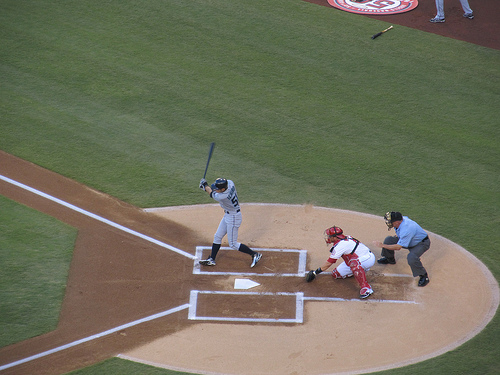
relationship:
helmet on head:
[209, 177, 229, 189] [210, 175, 233, 194]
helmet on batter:
[209, 177, 229, 189] [196, 171, 266, 274]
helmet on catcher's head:
[321, 227, 347, 241] [320, 225, 351, 246]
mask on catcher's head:
[322, 229, 336, 248] [320, 225, 351, 246]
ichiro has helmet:
[196, 171, 266, 274] [209, 177, 229, 189]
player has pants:
[196, 171, 266, 274] [211, 211, 246, 256]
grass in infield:
[1, 194, 79, 357] [1, 148, 211, 372]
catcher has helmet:
[298, 225, 381, 305] [321, 227, 347, 241]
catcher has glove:
[298, 225, 381, 305] [300, 264, 314, 287]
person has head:
[196, 171, 266, 274] [210, 175, 233, 194]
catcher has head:
[298, 225, 381, 305] [320, 225, 351, 246]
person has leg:
[196, 171, 266, 274] [225, 217, 265, 273]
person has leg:
[196, 171, 266, 274] [199, 216, 232, 267]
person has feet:
[196, 171, 266, 274] [195, 252, 267, 275]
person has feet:
[374, 209, 435, 289] [379, 249, 431, 290]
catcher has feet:
[298, 225, 381, 305] [355, 283, 377, 302]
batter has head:
[196, 171, 266, 274] [210, 175, 233, 194]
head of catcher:
[320, 225, 351, 246] [298, 225, 381, 305]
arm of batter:
[193, 177, 231, 204] [196, 171, 266, 274]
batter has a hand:
[196, 171, 266, 274] [197, 177, 209, 189]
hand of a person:
[372, 237, 388, 252] [374, 209, 435, 289]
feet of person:
[379, 249, 431, 290] [374, 209, 435, 289]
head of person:
[381, 208, 408, 229] [374, 209, 435, 289]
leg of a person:
[405, 240, 433, 289] [374, 209, 435, 289]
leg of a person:
[376, 235, 403, 267] [374, 209, 435, 289]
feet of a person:
[379, 249, 431, 290] [374, 209, 435, 289]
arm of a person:
[373, 239, 411, 252] [374, 209, 435, 289]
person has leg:
[374, 209, 435, 289] [376, 235, 403, 267]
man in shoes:
[374, 209, 435, 289] [379, 249, 431, 290]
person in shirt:
[374, 209, 435, 289] [391, 217, 429, 252]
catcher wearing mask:
[298, 225, 381, 305] [322, 230, 332, 248]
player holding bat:
[196, 171, 266, 274] [201, 137, 218, 188]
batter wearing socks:
[196, 171, 266, 274] [205, 241, 259, 268]